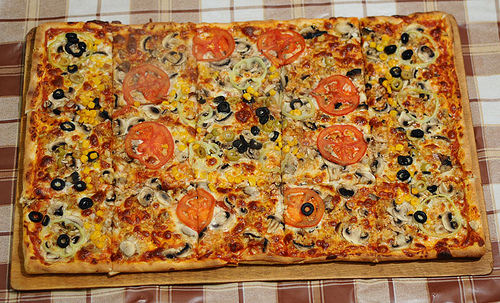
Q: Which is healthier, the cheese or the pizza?
A: The cheese is healthier than the pizza.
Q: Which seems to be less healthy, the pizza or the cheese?
A: The pizza is less healthy than the cheese.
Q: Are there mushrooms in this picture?
A: Yes, there are mushrooms.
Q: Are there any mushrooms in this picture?
A: Yes, there are mushrooms.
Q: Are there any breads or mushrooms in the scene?
A: Yes, there are mushrooms.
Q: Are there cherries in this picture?
A: No, there are no cherries.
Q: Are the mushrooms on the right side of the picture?
A: Yes, the mushrooms are on the right of the image.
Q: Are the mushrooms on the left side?
A: No, the mushrooms are on the right of the image.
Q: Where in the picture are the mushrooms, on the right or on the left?
A: The mushrooms are on the right of the image.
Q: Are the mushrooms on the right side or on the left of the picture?
A: The mushrooms are on the right of the image.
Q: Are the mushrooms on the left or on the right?
A: The mushrooms are on the right of the image.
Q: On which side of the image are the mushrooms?
A: The mushrooms are on the right of the image.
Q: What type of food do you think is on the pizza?
A: The food is mushrooms.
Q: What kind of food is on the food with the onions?
A: The food is mushrooms.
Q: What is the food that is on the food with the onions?
A: The food is mushrooms.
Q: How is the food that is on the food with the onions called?
A: The food is mushrooms.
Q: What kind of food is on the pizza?
A: The food is mushrooms.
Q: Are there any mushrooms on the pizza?
A: Yes, there are mushrooms on the pizza.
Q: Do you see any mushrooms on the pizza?
A: Yes, there are mushrooms on the pizza.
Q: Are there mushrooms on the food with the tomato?
A: Yes, there are mushrooms on the pizza.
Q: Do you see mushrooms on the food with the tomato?
A: Yes, there are mushrooms on the pizza.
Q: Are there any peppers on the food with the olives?
A: No, there are mushrooms on the pizza.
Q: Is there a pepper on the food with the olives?
A: No, there are mushrooms on the pizza.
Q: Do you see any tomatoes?
A: Yes, there are tomatoes.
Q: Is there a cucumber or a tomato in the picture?
A: Yes, there are tomatoes.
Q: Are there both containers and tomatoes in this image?
A: No, there are tomatoes but no containers.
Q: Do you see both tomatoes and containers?
A: No, there are tomatoes but no containers.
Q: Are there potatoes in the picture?
A: No, there are no potatoes.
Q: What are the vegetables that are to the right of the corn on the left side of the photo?
A: The vegetables are tomatoes.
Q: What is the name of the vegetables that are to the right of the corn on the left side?
A: The vegetables are tomatoes.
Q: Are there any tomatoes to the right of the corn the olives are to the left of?
A: Yes, there are tomatoes to the right of the corn.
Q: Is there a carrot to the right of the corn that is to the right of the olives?
A: No, there are tomatoes to the right of the corn.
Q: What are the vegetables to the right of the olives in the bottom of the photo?
A: The vegetables are tomatoes.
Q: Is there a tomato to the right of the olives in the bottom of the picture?
A: Yes, there are tomatoes to the right of the olives.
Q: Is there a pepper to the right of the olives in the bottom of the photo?
A: No, there are tomatoes to the right of the olives.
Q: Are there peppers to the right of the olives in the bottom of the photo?
A: No, there are tomatoes to the right of the olives.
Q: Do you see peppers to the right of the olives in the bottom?
A: No, there are tomatoes to the right of the olives.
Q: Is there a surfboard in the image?
A: No, there are no surfboards.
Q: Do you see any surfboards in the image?
A: No, there are no surfboards.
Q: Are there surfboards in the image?
A: No, there are no surfboards.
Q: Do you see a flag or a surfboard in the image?
A: No, there are no surfboards or flags.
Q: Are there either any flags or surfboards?
A: No, there are no surfboards or flags.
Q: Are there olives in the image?
A: Yes, there are olives.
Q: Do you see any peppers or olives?
A: Yes, there are olives.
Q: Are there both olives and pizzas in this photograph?
A: Yes, there are both olives and a pizza.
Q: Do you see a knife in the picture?
A: No, there are no knives.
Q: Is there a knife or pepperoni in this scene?
A: No, there are no knives or pepperoni.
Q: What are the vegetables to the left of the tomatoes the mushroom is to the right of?
A: The vegetables are olives.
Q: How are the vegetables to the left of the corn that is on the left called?
A: The vegetables are olives.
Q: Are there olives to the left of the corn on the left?
A: Yes, there are olives to the left of the corn.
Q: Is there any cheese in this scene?
A: Yes, there is cheese.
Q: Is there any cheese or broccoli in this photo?
A: Yes, there is cheese.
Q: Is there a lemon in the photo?
A: No, there are no lemons.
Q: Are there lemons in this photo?
A: No, there are no lemons.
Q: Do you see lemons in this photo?
A: No, there are no lemons.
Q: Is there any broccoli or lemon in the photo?
A: No, there are no lemons or broccoli.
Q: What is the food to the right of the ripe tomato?
A: The food is cheese.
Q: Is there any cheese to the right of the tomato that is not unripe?
A: Yes, there is cheese to the right of the tomato.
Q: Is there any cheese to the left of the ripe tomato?
A: No, the cheese is to the right of the tomato.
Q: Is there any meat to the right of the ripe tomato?
A: No, there is cheese to the right of the tomato.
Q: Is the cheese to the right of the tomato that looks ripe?
A: Yes, the cheese is to the right of the tomato.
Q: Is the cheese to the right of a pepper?
A: No, the cheese is to the right of the tomato.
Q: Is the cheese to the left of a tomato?
A: No, the cheese is to the right of a tomato.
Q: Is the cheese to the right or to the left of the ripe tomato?
A: The cheese is to the right of the tomato.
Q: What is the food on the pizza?
A: The food is cheese.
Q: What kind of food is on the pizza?
A: The food is cheese.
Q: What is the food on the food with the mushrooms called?
A: The food is cheese.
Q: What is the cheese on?
A: The cheese is on the pizza.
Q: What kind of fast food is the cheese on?
A: The cheese is on the pizza.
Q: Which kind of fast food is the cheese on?
A: The cheese is on the pizza.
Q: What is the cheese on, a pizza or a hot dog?
A: The cheese is on a pizza.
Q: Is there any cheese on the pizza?
A: Yes, there is cheese on the pizza.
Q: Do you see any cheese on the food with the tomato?
A: Yes, there is cheese on the pizza.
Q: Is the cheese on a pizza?
A: Yes, the cheese is on a pizza.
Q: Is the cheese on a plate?
A: No, the cheese is on a pizza.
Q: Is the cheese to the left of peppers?
A: No, the cheese is to the left of the olives.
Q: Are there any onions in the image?
A: Yes, there are onions.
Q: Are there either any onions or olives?
A: Yes, there are onions.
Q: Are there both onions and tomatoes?
A: Yes, there are both onions and a tomato.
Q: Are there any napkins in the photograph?
A: No, there are no napkins.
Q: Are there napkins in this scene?
A: No, there are no napkins.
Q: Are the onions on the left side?
A: Yes, the onions are on the left of the image.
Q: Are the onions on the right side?
A: No, the onions are on the left of the image.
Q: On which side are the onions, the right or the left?
A: The onions are on the left of the image.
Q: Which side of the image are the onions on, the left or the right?
A: The onions are on the left of the image.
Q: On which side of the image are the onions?
A: The onions are on the left of the image.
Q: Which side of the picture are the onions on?
A: The onions are on the left of the image.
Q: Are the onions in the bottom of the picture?
A: Yes, the onions are in the bottom of the image.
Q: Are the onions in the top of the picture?
A: No, the onions are in the bottom of the image.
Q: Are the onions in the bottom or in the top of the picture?
A: The onions are in the bottom of the image.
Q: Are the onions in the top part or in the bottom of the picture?
A: The onions are in the bottom of the image.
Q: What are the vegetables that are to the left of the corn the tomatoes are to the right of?
A: The vegetables are onions.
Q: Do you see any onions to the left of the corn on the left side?
A: Yes, there are onions to the left of the corn.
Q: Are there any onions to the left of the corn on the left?
A: Yes, there are onions to the left of the corn.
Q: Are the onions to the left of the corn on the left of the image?
A: Yes, the onions are to the left of the corn.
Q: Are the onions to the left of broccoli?
A: No, the onions are to the left of the corn.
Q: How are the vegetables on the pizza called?
A: The vegetables are onions.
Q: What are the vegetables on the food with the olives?
A: The vegetables are onions.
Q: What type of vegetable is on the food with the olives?
A: The vegetables are onions.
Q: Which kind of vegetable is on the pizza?
A: The vegetables are onions.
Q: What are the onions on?
A: The onions are on the pizza.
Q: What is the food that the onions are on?
A: The food is a pizza.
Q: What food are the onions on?
A: The onions are on the pizza.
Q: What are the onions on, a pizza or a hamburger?
A: The onions are on a pizza.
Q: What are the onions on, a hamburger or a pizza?
A: The onions are on a pizza.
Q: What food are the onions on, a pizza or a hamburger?
A: The onions are on a pizza.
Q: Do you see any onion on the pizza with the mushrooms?
A: Yes, there are onions on the pizza.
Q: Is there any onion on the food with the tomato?
A: Yes, there are onions on the pizza.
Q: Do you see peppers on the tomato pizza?
A: No, there are onions on the pizza.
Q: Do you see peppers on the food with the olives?
A: No, there are onions on the pizza.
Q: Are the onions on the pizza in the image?
A: Yes, the onions are on the pizza.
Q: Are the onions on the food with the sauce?
A: Yes, the onions are on the pizza.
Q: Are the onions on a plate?
A: No, the onions are on the pizza.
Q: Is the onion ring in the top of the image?
A: Yes, the onion ring is in the top of the image.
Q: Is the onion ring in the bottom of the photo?
A: No, the onion ring is in the top of the image.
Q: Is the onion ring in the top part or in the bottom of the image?
A: The onion ring is in the top of the image.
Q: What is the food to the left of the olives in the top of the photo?
A: The food is an onion ring.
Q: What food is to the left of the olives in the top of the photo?
A: The food is an onion ring.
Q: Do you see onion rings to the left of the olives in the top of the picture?
A: Yes, there is an onion ring to the left of the olives.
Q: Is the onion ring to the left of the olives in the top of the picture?
A: Yes, the onion ring is to the left of the olives.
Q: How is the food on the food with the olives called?
A: The food is an onion ring.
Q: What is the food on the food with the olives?
A: The food is an onion ring.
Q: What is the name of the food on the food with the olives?
A: The food is an onion ring.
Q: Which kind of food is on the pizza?
A: The food is an onion ring.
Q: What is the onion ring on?
A: The onion ring is on the pizza.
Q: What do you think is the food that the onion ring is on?
A: The food is a pizza.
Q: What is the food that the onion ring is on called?
A: The food is a pizza.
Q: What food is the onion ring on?
A: The onion ring is on the pizza.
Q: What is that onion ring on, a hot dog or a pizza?
A: The onion ring is on a pizza.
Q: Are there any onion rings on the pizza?
A: Yes, there is an onion ring on the pizza.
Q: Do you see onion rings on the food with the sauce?
A: Yes, there is an onion ring on the pizza.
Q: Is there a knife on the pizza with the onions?
A: No, there is an onion ring on the pizza.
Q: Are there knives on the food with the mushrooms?
A: No, there is an onion ring on the pizza.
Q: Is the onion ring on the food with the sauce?
A: Yes, the onion ring is on the pizza.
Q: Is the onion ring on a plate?
A: No, the onion ring is on the pizza.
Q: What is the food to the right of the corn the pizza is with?
A: The food is an onion ring.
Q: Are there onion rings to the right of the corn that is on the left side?
A: Yes, there is an onion ring to the right of the corn.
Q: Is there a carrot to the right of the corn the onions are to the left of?
A: No, there is an onion ring to the right of the corn.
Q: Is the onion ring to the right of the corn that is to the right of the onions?
A: Yes, the onion ring is to the right of the corn.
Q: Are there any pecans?
A: No, there are no pecans.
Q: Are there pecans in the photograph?
A: No, there are no pecans.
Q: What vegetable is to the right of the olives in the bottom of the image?
A: The vegetable is corn.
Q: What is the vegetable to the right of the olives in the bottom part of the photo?
A: The vegetable is corn.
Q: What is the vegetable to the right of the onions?
A: The vegetable is corn.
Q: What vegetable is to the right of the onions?
A: The vegetable is corn.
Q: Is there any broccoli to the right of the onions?
A: No, there is corn to the right of the onions.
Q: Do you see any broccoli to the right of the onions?
A: No, there is corn to the right of the onions.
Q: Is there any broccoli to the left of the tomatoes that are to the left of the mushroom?
A: No, there is corn to the left of the tomatoes.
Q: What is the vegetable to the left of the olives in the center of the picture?
A: The vegetable is corn.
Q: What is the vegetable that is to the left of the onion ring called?
A: The vegetable is corn.